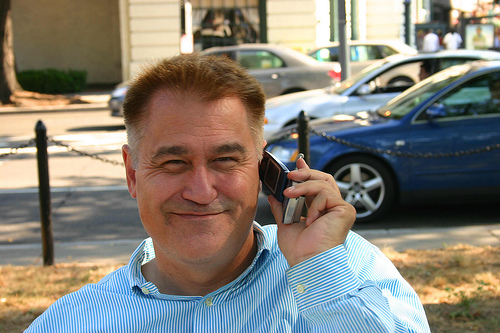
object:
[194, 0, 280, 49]
window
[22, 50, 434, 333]
man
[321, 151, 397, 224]
black tire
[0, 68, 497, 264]
street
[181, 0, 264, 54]
store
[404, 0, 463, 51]
store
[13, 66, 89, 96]
hedges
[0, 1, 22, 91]
tree trunk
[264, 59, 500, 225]
blue car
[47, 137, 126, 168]
chain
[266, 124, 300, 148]
chain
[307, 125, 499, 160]
chain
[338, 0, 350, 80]
pole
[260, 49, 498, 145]
car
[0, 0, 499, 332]
background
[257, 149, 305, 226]
cell phone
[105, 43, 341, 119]
car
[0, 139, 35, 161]
chain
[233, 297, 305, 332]
striped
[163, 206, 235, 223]
smile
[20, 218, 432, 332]
shirt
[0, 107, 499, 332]
ground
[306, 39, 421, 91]
car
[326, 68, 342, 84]
taillight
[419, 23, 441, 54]
people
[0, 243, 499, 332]
grass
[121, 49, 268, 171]
hair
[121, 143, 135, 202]
ear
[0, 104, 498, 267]
road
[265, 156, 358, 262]
hand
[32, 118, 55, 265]
post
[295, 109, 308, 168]
post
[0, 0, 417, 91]
building